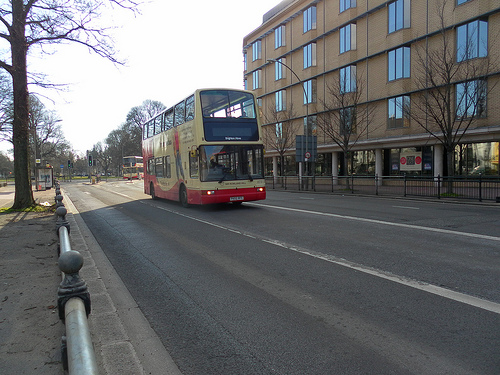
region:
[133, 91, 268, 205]
a double decker bus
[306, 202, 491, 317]
a couple of line on the pavement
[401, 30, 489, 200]
a tall dry tree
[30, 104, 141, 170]
many trees in the distance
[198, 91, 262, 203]
the front view of the bus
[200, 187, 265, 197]
the bus headlights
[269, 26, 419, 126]
some crystal windows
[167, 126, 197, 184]
one Ad on the lateral of the bus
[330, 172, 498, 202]
a green metal fence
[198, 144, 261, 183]
the bus windshields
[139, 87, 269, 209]
red and yellow double decker bus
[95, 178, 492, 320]
white lines on the roadway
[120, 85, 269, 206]
two red and yellow buese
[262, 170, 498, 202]
a black metal fence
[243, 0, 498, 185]
a building with many windows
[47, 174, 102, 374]
a silver and black metal fence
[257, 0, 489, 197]
a line of trees on the sidewalk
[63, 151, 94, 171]
green illuminated traffic control light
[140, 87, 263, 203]
red and yellow bus with illuminated headlights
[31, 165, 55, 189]
a white sign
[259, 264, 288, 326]
This photo has a dark black patch of asphalt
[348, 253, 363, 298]
There is a white line that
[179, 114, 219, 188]
There is a bus that is visible here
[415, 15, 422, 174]
There is a dark black fence that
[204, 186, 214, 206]
There is a light here that is quite visible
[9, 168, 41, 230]
There is a brown trunk that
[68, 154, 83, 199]
There are stop lights that are visible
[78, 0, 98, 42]
There is a dark brown tree trunk here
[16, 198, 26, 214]
There is a dark green patch of grass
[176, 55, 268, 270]
There is a photo that is taken in Ohio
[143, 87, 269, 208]
A double decker bus on the road.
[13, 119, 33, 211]
Part of a tree trunk.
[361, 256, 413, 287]
Part of a white line.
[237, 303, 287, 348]
Part of the road.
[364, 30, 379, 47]
Part of a building.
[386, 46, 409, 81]
A window on the building.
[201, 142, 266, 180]
The front window on the bus.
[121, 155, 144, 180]
A bus in the distance.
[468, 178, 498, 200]
Part of a fence.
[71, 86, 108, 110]
Part of the sky.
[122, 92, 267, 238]
red and yellow bus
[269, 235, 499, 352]
white line on road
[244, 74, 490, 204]
bare trees behind bus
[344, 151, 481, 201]
black fence near trees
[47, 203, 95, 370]
grey rail on sidewalk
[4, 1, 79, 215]
tall and bare tree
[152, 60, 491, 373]
road is dark grey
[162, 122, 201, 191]
person on side of bus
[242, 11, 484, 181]
dark brown apartment building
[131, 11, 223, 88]
bright and white sky